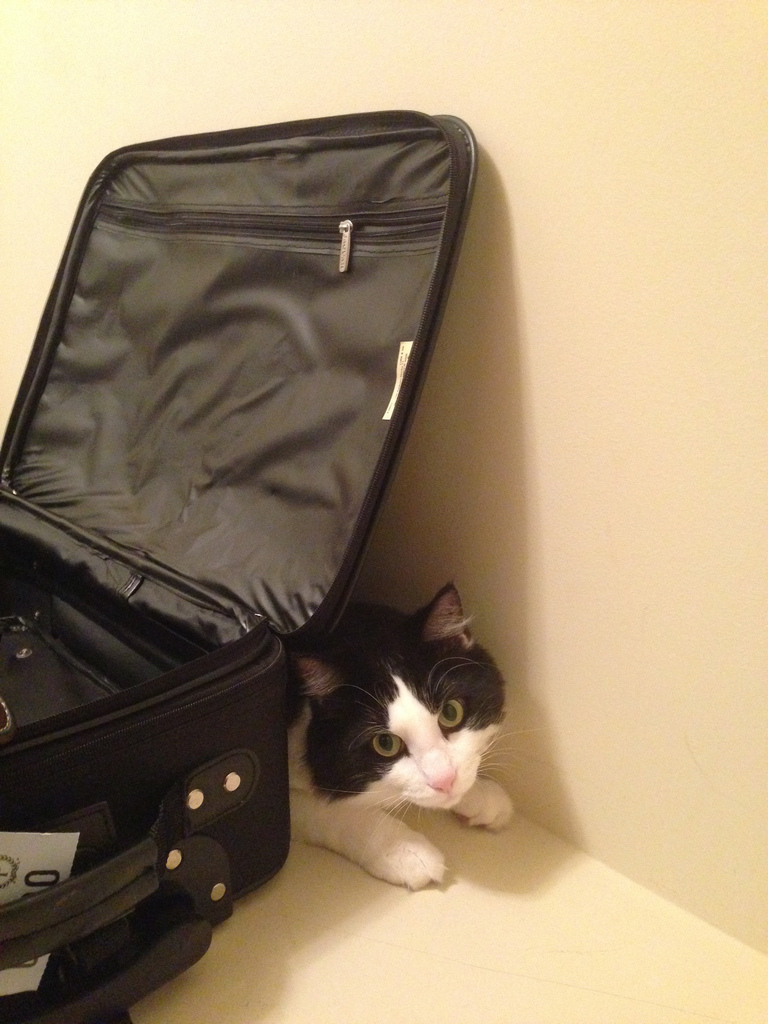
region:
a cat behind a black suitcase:
[88, 504, 537, 908]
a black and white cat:
[274, 576, 513, 894]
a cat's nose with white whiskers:
[370, 735, 521, 827]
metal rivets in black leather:
[182, 745, 254, 827]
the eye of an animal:
[365, 721, 404, 760]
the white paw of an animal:
[326, 805, 444, 896]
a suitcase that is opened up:
[0, 102, 477, 1006]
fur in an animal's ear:
[408, 584, 478, 656]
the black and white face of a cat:
[311, 637, 506, 799]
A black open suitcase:
[0, 100, 459, 1017]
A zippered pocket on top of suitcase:
[96, 185, 414, 267]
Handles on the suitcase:
[9, 784, 247, 1008]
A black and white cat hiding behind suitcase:
[290, 588, 532, 888]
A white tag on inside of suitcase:
[381, 321, 416, 435]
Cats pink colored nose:
[417, 750, 470, 799]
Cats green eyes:
[361, 683, 480, 765]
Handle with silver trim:
[166, 761, 274, 922]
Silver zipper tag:
[327, 206, 366, 276]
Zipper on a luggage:
[329, 217, 359, 275]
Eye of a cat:
[438, 689, 472, 737]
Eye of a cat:
[369, 730, 409, 760]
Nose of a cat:
[429, 769, 459, 798]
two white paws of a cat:
[284, 769, 524, 892]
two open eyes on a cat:
[359, 687, 484, 768]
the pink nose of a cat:
[415, 765, 458, 795]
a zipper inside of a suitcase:
[83, 189, 452, 274]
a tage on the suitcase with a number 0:
[0, 814, 89, 999]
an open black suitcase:
[3, 103, 487, 1020]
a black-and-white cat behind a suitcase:
[291, 574, 533, 900]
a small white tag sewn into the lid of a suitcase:
[375, 331, 424, 435]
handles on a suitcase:
[1, 740, 266, 1021]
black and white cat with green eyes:
[286, 583, 518, 888]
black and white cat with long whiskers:
[282, 580, 509, 889]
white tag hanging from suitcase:
[4, 829, 75, 992]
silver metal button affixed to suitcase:
[187, 789, 206, 810]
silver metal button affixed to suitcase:
[224, 772, 241, 790]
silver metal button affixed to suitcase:
[211, 882, 226, 900]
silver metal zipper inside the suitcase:
[334, 219, 354, 270]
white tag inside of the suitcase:
[381, 339, 412, 424]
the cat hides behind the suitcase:
[275, 570, 524, 893]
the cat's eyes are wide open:
[368, 693, 474, 762]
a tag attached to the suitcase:
[0, 817, 86, 998]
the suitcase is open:
[0, 110, 485, 1019]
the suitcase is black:
[0, 103, 481, 1020]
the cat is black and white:
[273, 573, 520, 898]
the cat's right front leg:
[283, 786, 450, 890]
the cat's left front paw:
[453, 768, 518, 837]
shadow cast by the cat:
[427, 687, 591, 900]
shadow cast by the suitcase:
[125, 136, 534, 1021]